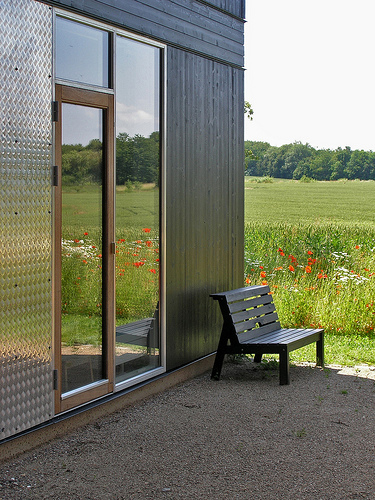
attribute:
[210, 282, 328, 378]
bench — gray, wooden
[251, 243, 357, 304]
flowers — red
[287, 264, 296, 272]
flower — orange, red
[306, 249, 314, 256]
flower — orange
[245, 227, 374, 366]
grass — green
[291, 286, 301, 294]
flower — white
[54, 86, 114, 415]
door — glass, glass paneled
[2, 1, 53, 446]
siding — metal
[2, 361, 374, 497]
patio — concrete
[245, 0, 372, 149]
sky — hazy, gray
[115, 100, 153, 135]
cloud — white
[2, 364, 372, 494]
gravel — gray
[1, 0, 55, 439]
panel — metal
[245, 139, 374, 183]
trees — green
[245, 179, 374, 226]
grass — green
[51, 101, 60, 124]
hinge — black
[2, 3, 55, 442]
metal surface — patterned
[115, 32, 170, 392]
window — reflecting